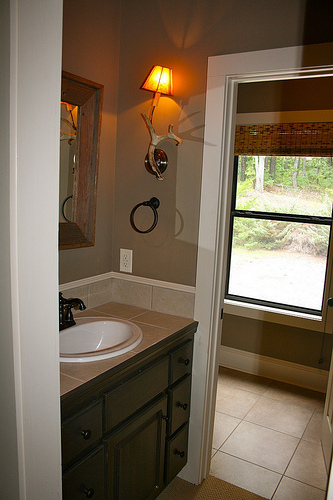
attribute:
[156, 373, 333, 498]
floor — tile, beige, tiled, white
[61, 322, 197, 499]
cupboard — brown, wooden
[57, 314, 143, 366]
sink — white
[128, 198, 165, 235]
handle — black, metal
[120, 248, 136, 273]
switch — plastic, electrical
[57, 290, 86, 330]
faucet — black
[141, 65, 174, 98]
shade — orange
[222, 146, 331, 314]
window — black, here, closed, brown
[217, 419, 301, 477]
tile — tan, square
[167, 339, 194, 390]
drawer — wooden, wood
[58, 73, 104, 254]
mirror — wooden, framed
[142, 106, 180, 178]
antler — tan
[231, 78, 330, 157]
blinds — up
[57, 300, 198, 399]
counter — tile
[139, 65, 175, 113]
light — on, yellow, orange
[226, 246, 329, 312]
grass — green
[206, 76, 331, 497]
door — open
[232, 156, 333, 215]
leaves — green